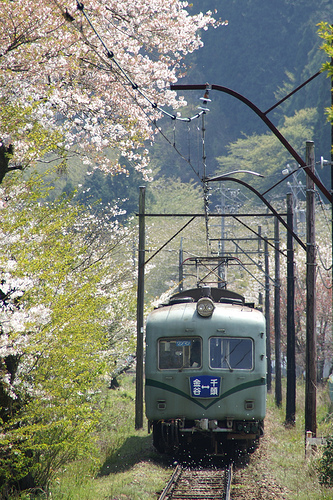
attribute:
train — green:
[133, 281, 274, 468]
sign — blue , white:
[187, 372, 222, 399]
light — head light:
[243, 399, 254, 412]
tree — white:
[12, 11, 204, 450]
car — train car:
[144, 287, 265, 460]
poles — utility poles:
[99, 145, 320, 312]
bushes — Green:
[0, 196, 145, 475]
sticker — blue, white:
[188, 376, 219, 398]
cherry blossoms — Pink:
[1, 2, 329, 456]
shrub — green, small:
[32, 43, 122, 213]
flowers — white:
[0, 1, 329, 498]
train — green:
[143, 285, 265, 452]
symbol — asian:
[189, 375, 221, 398]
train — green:
[144, 281, 266, 465]